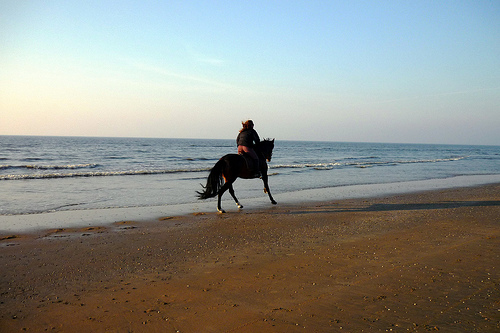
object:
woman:
[236, 119, 264, 178]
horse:
[194, 137, 279, 214]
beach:
[0, 173, 500, 332]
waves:
[0, 163, 99, 170]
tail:
[194, 159, 226, 200]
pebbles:
[186, 284, 190, 288]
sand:
[333, 219, 500, 333]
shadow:
[224, 200, 500, 215]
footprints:
[119, 224, 138, 230]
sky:
[0, 0, 500, 146]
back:
[237, 129, 253, 145]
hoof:
[238, 204, 244, 209]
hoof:
[218, 208, 226, 213]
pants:
[238, 144, 260, 174]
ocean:
[0, 134, 500, 232]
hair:
[238, 119, 254, 132]